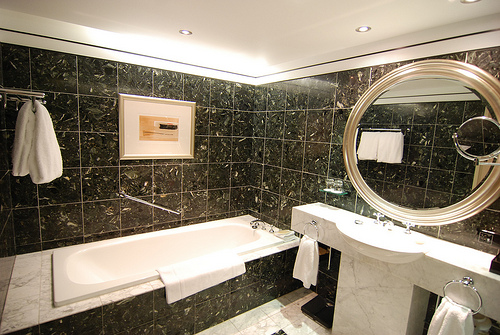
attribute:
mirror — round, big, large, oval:
[341, 59, 499, 227]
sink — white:
[334, 218, 427, 263]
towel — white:
[291, 235, 320, 290]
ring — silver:
[301, 221, 320, 242]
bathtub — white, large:
[52, 213, 300, 307]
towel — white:
[11, 101, 63, 185]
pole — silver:
[1, 88, 49, 113]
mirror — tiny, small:
[451, 115, 499, 166]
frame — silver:
[116, 92, 198, 161]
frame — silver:
[341, 58, 498, 225]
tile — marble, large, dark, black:
[3, 41, 496, 333]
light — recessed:
[178, 1, 482, 36]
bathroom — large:
[3, 1, 495, 333]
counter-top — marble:
[293, 202, 499, 280]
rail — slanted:
[117, 189, 182, 216]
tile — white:
[195, 288, 329, 334]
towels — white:
[355, 129, 405, 165]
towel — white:
[156, 246, 247, 305]